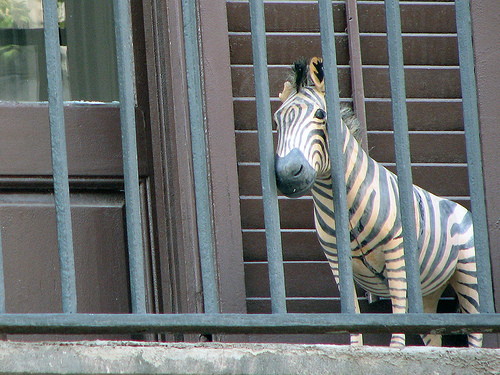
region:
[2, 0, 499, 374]
a scene during the day time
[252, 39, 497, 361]
a wooden zebra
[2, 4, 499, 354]
a black guardrail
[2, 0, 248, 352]
a brown door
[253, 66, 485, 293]
a statue of a zebra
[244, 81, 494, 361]
a statue with stripes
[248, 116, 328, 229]
a black nose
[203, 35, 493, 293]
a statue with black and white stripes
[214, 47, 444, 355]
a statue standing outside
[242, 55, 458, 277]
a zebra standing outside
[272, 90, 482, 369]
a zebra with stripes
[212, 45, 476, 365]
a small animal statue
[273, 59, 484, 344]
A statue of a zebra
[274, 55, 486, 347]
A minature zebra statue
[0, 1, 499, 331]
A metal fense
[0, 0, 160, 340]
A brown wooden door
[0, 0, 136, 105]
A window in a door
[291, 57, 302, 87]
A zebra statue with hair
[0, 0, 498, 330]
A zebra statue behind bars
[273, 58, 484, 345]
A zebra statue with four legs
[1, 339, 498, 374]
A floor made of concrete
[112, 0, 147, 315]
A metal bar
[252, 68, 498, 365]
zebra in a cage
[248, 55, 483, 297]
a statue of a zebra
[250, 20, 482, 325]
a small zebra statue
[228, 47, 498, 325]
a zebra on a balcony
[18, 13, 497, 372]
a balcony fence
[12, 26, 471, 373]
a metal balcony fence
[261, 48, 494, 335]
a statue of an animal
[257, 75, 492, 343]
black and white stripes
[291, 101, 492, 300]
zebra with white stripes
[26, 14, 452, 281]
this is a zebra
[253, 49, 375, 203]
the zebra is looking at the camera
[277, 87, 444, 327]
the zebra is striped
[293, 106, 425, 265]
the zebra is white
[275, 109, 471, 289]
the zebra is black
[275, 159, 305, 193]
the nose is black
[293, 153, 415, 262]
the zebra is black and white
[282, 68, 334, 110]
the zebra has a mane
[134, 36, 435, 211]
the bars are blue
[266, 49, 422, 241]
the zebra's head is between bars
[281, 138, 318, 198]
Nose of a replica zebra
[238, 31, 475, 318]
Replica zebra looking through a fence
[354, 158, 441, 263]
Black and white stripes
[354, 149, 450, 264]
Black and white stripes of a replica zebra